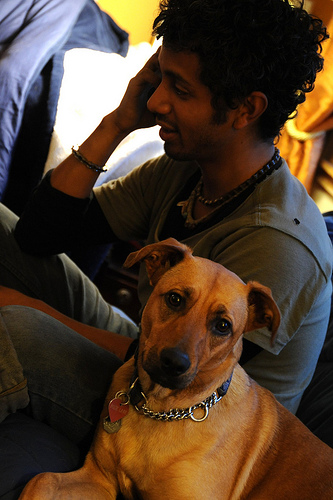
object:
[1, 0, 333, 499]
guy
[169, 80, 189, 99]
eye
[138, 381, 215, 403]
neck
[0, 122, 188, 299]
arm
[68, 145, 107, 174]
bracelet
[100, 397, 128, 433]
dog tags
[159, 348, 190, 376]
nose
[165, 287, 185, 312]
eye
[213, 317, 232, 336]
eye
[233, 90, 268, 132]
ear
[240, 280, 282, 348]
ear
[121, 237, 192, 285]
ear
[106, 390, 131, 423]
heart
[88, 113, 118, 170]
wrist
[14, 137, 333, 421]
shirt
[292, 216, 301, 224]
hole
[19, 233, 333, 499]
dog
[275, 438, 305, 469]
brown fur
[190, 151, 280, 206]
necklace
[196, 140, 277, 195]
neck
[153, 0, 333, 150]
hair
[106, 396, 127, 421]
charm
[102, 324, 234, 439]
collar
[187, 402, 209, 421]
loop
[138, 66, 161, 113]
phone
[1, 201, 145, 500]
jeans